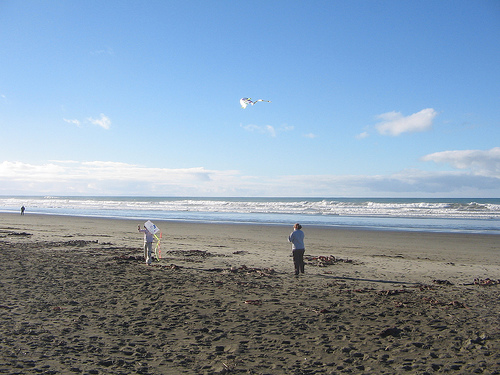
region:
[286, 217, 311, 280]
woman wearing black pants and tan sweater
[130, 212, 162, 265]
person wearing tan pants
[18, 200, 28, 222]
person walking along beaach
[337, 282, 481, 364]
tan prints in beach sand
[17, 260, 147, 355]
tan prints in beach sand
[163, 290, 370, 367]
tan prints in beach sand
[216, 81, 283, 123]
white kite flown in air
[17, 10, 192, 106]
clear blue cloudless sky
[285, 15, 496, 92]
clear blue cloudless sky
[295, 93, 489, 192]
white clouds against blue sky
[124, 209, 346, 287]
Two people on a beach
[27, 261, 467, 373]
Tracks are in the sand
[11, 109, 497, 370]
Photo was taken in the daytime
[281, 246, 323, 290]
Person is wearing dark colored pants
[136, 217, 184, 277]
Person is holding a kite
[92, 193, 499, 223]
A large body of water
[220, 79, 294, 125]
A kite is in the air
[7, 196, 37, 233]
A person is in the far background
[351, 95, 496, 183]
Clouds are in the sky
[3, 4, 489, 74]
The sky is blue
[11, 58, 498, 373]
Picture was taken at a beach.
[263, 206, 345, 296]
Woman flying a kite.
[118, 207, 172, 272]
Person holding a kite.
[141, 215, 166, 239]
The kite is white.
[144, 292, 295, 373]
The sand is brown.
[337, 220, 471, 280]
The sand is light brown.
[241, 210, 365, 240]
The water is blue.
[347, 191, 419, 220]
The wave is white.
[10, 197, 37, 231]
A person standing on the edge of the beach.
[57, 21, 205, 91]
The sky is blue.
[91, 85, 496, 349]
photo was taken outdoors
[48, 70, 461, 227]
sky is blue and white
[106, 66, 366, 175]
sky is blue and white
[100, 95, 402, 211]
sky is blue and white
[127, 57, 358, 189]
sky is blue and white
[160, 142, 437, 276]
sky is blue and white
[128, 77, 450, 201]
sky is blue and white